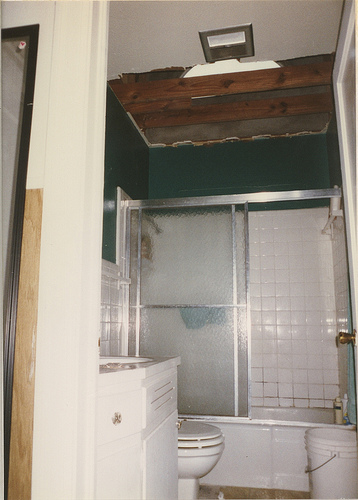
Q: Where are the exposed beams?
A: Ceiling.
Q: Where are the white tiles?
A: Bottom half of wall.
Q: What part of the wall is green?
A: Top half.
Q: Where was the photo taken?
A: Bathroom.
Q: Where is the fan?
A: Next to exposed beams.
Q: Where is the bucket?
A: In front of toilet.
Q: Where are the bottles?
A: In shower.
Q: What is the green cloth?
A: Wash cloth.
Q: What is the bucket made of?
A: Plastic.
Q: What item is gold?
A: Door handle.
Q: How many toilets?
A: One.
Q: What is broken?
A: Ceiling.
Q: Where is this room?
A: In the house.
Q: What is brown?
A: Wood.